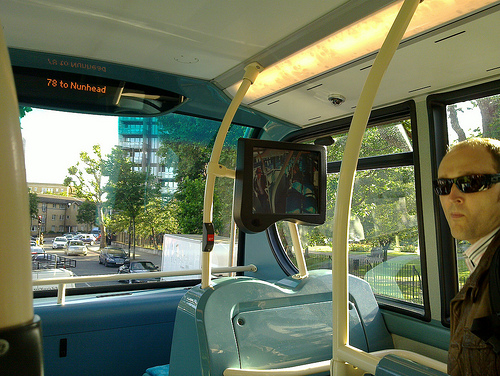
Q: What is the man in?
A: A bus.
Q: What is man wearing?
A: Sunglasses.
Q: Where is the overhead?
A: On bus.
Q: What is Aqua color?
A: Seat.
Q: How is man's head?
A: Bald.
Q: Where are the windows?
A: On building.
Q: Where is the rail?
A: On bus.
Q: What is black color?
A: TV.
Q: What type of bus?
A: City.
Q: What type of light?
A: Overhead.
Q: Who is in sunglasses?
A: A man.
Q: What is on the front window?
A: Rail.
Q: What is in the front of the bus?
A: Downtown.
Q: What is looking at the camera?
A: Passenger.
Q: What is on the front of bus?
A: Tv.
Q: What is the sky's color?
A: White.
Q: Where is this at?
A: Inside bus.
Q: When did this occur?
A: During the day time.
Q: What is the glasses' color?
A: Black.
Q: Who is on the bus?
A: A man with short hair.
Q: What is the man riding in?
A: A bus.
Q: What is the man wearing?
A: A jacket.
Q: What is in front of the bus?
A: Traffic.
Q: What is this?
A: Bus.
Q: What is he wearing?
A: Glasses.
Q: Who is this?
A: Man.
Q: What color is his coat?
A: Brown.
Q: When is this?
A: Daytime.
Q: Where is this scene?
A: On a bus.